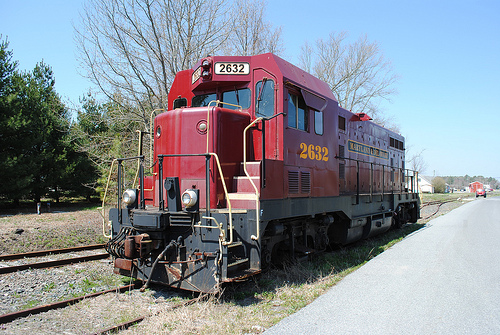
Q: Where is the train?
A: In the train tracks.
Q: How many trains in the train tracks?
A: One.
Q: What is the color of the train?
A: Red.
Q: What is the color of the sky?
A: Blue.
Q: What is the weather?
A: Sunny.